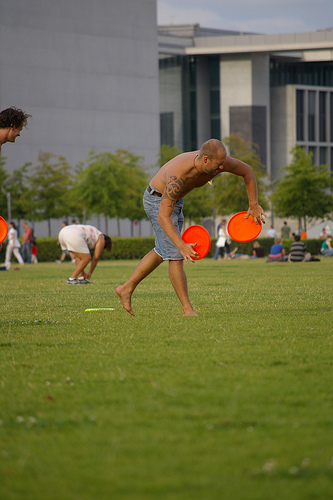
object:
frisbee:
[227, 211, 263, 244]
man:
[116, 139, 268, 317]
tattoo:
[161, 176, 185, 208]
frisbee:
[85, 308, 116, 312]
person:
[288, 235, 306, 263]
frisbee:
[181, 225, 211, 261]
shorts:
[143, 182, 185, 260]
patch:
[0, 315, 80, 334]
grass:
[0, 257, 331, 500]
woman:
[58, 224, 112, 284]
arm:
[158, 173, 187, 248]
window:
[296, 88, 305, 140]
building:
[155, 16, 333, 180]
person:
[21, 220, 32, 264]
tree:
[267, 146, 331, 228]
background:
[1, 0, 320, 160]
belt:
[147, 184, 163, 197]